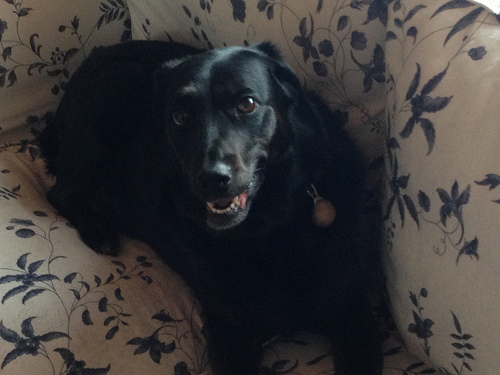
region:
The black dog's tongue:
[236, 187, 249, 209]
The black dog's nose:
[199, 163, 236, 185]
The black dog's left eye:
[235, 93, 259, 116]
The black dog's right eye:
[169, 102, 191, 127]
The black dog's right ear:
[130, 58, 170, 143]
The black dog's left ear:
[269, 59, 339, 159]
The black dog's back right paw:
[49, 186, 126, 261]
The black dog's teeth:
[204, 197, 240, 216]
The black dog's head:
[151, 42, 296, 238]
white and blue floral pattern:
[0, 244, 170, 367]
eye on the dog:
[168, 105, 195, 129]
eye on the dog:
[232, 92, 260, 115]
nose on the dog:
[192, 155, 237, 187]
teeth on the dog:
[200, 195, 249, 219]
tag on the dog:
[297, 182, 347, 227]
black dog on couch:
[47, 30, 402, 372]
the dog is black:
[45, 34, 390, 365]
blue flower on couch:
[391, 65, 458, 141]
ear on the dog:
[252, 54, 308, 120]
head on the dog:
[151, 41, 316, 241]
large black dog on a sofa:
[1, 4, 498, 369]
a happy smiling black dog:
[41, 38, 405, 373]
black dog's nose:
[204, 161, 231, 183]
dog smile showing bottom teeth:
[196, 181, 251, 222]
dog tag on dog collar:
[302, 176, 337, 228]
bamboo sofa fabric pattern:
[4, 246, 73, 315]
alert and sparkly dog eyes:
[167, 88, 262, 128]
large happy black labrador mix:
[38, 32, 416, 369]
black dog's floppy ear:
[266, 54, 307, 146]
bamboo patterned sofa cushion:
[0, 96, 201, 373]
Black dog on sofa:
[48, 30, 390, 373]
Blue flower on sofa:
[434, 173, 476, 252]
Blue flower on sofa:
[406, 306, 435, 341]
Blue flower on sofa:
[288, 12, 321, 63]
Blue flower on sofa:
[0, 316, 71, 372]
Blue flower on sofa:
[125, 328, 178, 365]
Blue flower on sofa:
[466, 42, 486, 61]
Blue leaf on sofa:
[449, 308, 463, 335]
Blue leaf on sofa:
[447, 330, 461, 341]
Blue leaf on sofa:
[461, 330, 473, 341]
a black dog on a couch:
[39, 41, 387, 369]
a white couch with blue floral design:
[1, 0, 498, 371]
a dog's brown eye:
[238, 95, 258, 112]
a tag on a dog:
[303, 178, 334, 226]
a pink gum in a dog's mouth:
[239, 190, 248, 207]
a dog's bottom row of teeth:
[204, 195, 240, 214]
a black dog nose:
[196, 163, 229, 186]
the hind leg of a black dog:
[42, 177, 123, 258]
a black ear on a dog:
[154, 54, 181, 126]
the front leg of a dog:
[324, 294, 383, 372]